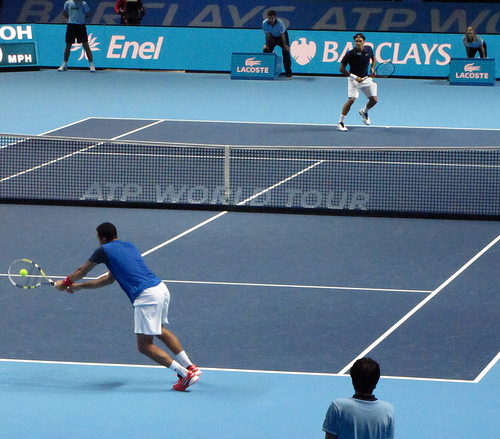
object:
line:
[335, 232, 500, 376]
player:
[54, 221, 200, 394]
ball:
[20, 269, 28, 278]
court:
[0, 69, 500, 439]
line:
[1, 357, 472, 386]